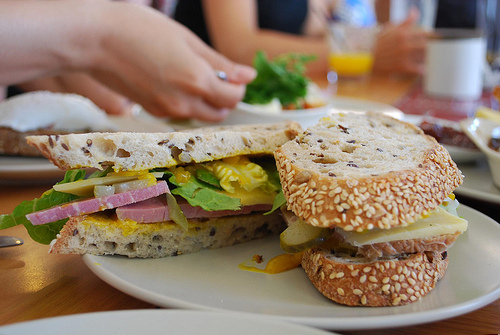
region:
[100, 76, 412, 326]
a sandwich on a plate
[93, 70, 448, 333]
a sandwich on a white plate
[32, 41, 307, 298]
a sandwich cut in half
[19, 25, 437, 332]
a plate with a sandiwhc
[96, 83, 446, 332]
a white plate with a sandwich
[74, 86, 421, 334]
a sandwich with lettuce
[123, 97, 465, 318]
a sanwich with cheese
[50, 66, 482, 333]
a sanwich on a table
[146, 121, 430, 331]
a plate with food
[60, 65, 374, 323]
food on a plate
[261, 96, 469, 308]
this is a bread sandwich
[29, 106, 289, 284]
this is a bread sandwich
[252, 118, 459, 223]
this is a slice of bread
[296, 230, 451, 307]
this is a slice of bread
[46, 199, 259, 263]
this is a slice of bread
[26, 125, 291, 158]
this is a slice of bread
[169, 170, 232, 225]
vegetables in the sandwich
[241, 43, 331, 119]
vegetables in the sandwich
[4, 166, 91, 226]
vegetables in the sandwich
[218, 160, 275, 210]
vegetables in the sandwich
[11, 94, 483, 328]
a plate of food on the table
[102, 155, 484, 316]
the plate is white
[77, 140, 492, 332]
the plate is round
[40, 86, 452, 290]
a sandwich on the plate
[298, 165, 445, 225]
sesame seeds on the edge of the bread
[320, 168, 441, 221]
the seeds are beige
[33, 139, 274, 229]
lettuce on the sandwich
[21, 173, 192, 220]
the meat is pink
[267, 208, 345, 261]
pickles are on the bread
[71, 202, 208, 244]
mustard is on the bread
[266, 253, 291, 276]
the mustard is yellow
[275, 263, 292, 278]
the mustard is on the plate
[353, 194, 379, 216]
the seeds are on the bread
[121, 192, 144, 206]
the meat is pink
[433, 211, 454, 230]
the cheese is white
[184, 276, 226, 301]
the plate is white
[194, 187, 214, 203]
the lettuce is green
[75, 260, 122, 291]
the plate is on the table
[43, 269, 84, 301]
the table is brown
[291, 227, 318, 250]
the pickle is falling out of the sandwich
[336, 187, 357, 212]
Sesame seeds on the bread.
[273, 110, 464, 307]
A small sandwich.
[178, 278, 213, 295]
Part of the white plate.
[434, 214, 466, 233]
Part of a slice of cheese.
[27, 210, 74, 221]
Part of a slice of meat.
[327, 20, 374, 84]
A glass of juice.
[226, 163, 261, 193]
Part of a piece of lettuce.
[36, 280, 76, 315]
Part of the table.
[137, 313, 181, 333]
Part of a plate.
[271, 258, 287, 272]
part of the mustard.